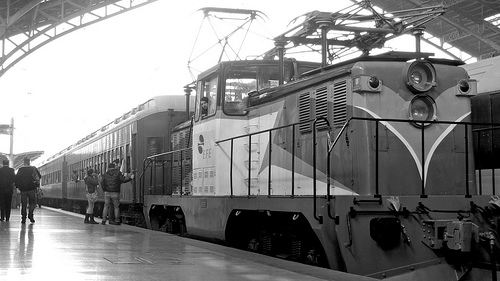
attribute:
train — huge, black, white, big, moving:
[181, 76, 470, 230]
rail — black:
[248, 126, 342, 186]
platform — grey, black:
[86, 233, 210, 278]